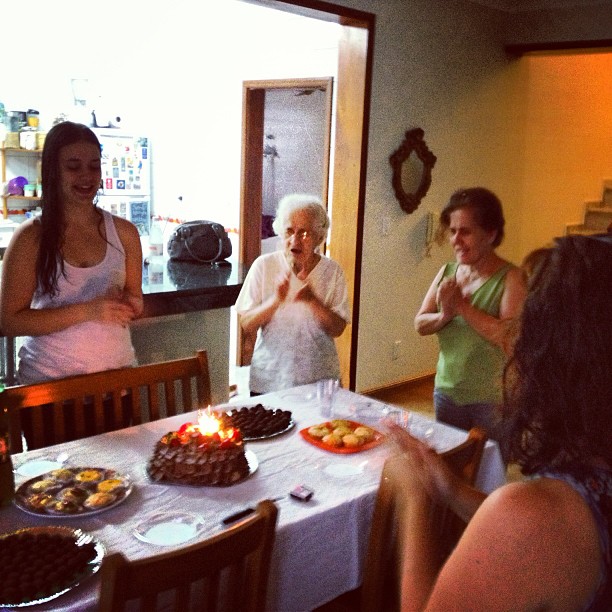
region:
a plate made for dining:
[18, 459, 141, 521]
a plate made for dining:
[292, 413, 382, 454]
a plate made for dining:
[196, 399, 298, 440]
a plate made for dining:
[8, 518, 98, 610]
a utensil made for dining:
[214, 492, 287, 521]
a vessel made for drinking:
[319, 374, 335, 411]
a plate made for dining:
[128, 508, 200, 548]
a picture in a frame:
[390, 121, 442, 210]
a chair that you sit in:
[70, 503, 274, 603]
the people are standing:
[0, 121, 611, 610]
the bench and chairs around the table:
[0, 350, 506, 610]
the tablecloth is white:
[0, 380, 507, 610]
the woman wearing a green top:
[412, 183, 526, 436]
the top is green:
[433, 257, 515, 406]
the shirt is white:
[230, 246, 349, 393]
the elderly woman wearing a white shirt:
[234, 190, 350, 398]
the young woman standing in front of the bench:
[0, 120, 210, 455]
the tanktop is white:
[18, 210, 136, 381]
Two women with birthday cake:
[149, 181, 530, 477]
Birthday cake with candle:
[141, 397, 265, 492]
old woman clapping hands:
[248, 190, 345, 330]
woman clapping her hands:
[412, 179, 520, 380]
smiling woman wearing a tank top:
[0, 102, 162, 363]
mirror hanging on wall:
[386, 120, 434, 216]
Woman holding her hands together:
[411, 180, 529, 392]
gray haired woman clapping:
[237, 186, 355, 381]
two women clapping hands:
[237, 189, 529, 365]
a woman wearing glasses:
[272, 223, 321, 243]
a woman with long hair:
[26, 123, 102, 297]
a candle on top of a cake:
[174, 405, 229, 450]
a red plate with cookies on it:
[304, 418, 381, 449]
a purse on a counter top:
[165, 216, 234, 270]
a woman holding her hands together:
[436, 274, 476, 322]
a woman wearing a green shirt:
[420, 265, 517, 396]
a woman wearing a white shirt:
[14, 214, 134, 367]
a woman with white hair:
[272, 191, 327, 246]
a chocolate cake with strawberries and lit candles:
[147, 405, 250, 485]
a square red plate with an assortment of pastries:
[298, 416, 386, 455]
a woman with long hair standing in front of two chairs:
[0, 118, 209, 451]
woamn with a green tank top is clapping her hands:
[414, 185, 528, 469]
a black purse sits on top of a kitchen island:
[1, 221, 247, 423]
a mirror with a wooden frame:
[388, 126, 437, 209]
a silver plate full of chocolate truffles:
[218, 404, 294, 440]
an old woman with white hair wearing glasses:
[239, 194, 349, 402]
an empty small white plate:
[132, 509, 208, 549]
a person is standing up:
[7, 130, 145, 420]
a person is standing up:
[421, 180, 518, 479]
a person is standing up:
[369, 246, 598, 610]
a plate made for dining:
[309, 417, 385, 453]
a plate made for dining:
[208, 395, 288, 446]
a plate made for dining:
[20, 460, 131, 516]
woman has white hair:
[260, 170, 356, 269]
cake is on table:
[148, 415, 259, 481]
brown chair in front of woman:
[6, 326, 233, 450]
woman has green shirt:
[437, 252, 512, 409]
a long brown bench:
[0, 347, 213, 458]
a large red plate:
[297, 415, 383, 456]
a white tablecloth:
[2, 377, 500, 610]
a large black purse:
[168, 219, 230, 265]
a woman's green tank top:
[436, 260, 515, 406]